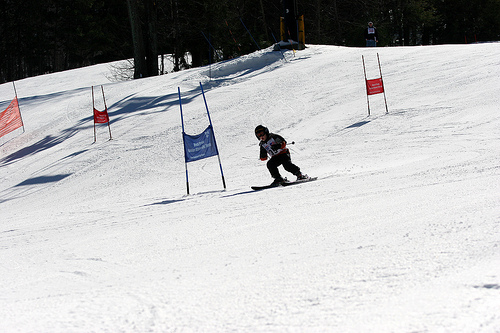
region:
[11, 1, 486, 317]
contestant in a downhill slalom race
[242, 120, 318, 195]
young skier makes his way down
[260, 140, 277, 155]
white bib identifying the contestant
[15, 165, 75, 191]
shadow of a marker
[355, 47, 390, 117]
red marker between two poles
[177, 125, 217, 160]
blue marker with writing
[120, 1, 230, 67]
trees at the edge of the course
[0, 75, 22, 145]
fence at the course's boundry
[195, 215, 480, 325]
hard packed snow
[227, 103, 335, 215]
skier with pole under his arms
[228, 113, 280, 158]
the head of a man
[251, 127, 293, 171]
the arms of a man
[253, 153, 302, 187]
the legs of a man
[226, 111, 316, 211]
a man on skis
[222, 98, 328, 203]
a man on the snow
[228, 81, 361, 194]
a man holding ski sticks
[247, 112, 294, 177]
a man wearing a coat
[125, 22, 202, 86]
the base of a tree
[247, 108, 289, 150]
a man wearing a hat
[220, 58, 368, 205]
a man skiing in the snow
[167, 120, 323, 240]
a skier on a slope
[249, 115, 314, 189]
skier wears black cloths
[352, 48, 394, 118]
a red sign on hill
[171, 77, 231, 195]
a blue sign on hill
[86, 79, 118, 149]
a red sign on hill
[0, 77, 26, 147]
an orange sign on hill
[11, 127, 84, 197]
shadows on the snow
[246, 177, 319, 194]
skies on the snow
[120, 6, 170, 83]
a trunk on top the hill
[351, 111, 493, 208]
marks of skis on the snow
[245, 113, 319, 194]
person on a pair of ski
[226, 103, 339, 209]
person ski down a snowy field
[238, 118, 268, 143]
head of a person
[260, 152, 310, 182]
legs of a person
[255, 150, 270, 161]
hand of a person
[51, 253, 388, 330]
a plain snowy field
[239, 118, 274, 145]
person wearing a hat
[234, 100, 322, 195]
person wearing a jacket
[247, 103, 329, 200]
person wearing dark bottom pant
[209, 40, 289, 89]
shadows from the tree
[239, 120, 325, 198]
a skier with a warm hat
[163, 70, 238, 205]
a blue gate to guide skiers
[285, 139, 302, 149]
the tip of a ski pole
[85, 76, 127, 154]
a red gate to guide skiers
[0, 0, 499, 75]
a stand of trees beyond the snow covered hill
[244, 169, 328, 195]
a pair of skis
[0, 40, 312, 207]
shadows cast on the snow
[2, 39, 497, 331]
a snow covered hillside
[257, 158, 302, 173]
the bent knees of a skier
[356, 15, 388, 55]
a skier with a white bib